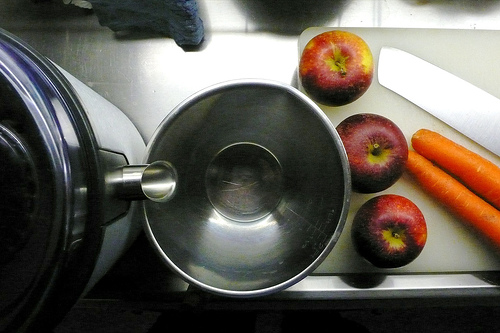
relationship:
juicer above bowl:
[3, 30, 158, 317] [130, 77, 357, 304]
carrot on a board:
[406, 155, 499, 241] [295, 23, 500, 275]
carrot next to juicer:
[411, 127, 499, 195] [3, 30, 158, 317]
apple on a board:
[299, 29, 372, 106] [295, 23, 500, 275]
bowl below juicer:
[130, 77, 357, 304] [3, 30, 158, 317]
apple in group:
[299, 29, 372, 106] [297, 28, 428, 269]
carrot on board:
[406, 155, 499, 241] [295, 23, 500, 275]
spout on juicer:
[103, 148, 177, 219] [3, 30, 158, 317]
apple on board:
[339, 113, 406, 193] [295, 23, 500, 275]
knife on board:
[374, 45, 500, 155] [295, 23, 500, 275]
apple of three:
[352, 194, 428, 268] [299, 29, 434, 262]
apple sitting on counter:
[299, 29, 372, 106] [2, 1, 500, 289]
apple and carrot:
[339, 113, 406, 193] [406, 155, 499, 241]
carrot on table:
[411, 127, 499, 195] [2, 1, 500, 289]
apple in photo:
[339, 113, 406, 193] [0, 1, 498, 330]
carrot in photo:
[406, 155, 499, 241] [0, 1, 498, 330]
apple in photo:
[299, 29, 372, 106] [0, 1, 498, 330]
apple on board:
[299, 29, 372, 106] [295, 23, 500, 275]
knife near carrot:
[374, 45, 500, 155] [411, 127, 499, 195]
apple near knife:
[339, 113, 406, 193] [374, 45, 500, 155]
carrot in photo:
[411, 127, 499, 195] [0, 1, 498, 330]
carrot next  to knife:
[406, 155, 499, 241] [374, 45, 500, 155]